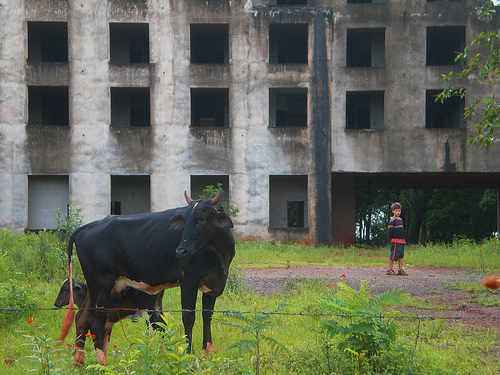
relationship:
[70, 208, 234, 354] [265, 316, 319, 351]
bull in grass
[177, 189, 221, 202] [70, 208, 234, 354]
horns on bull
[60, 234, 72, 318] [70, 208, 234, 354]
tail on bull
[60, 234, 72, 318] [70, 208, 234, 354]
tail of bull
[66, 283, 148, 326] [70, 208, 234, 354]
calf near bull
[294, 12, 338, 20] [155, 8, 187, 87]
concrete on wall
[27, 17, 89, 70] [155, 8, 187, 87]
window on wall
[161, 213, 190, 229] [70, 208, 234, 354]
ear of bull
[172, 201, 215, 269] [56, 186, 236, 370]
head of bull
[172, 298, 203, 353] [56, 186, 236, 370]
leg of bull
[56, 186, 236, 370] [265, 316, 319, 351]
bull in grass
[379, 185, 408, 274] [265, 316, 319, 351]
kid on grass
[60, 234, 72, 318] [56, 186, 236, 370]
tail on bull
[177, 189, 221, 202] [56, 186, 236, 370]
horns on bull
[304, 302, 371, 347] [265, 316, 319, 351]
fern in grass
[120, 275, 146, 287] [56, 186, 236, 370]
belly on bull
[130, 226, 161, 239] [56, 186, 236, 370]
rib of bull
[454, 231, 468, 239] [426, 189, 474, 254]
wire on gate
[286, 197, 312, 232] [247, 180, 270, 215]
door inside porch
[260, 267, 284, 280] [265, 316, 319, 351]
dirt in grass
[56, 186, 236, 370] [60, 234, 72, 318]
bull has tail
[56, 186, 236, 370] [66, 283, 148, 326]
bull near calf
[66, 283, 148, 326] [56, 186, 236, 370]
calf near bull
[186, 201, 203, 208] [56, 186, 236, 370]
spot on bull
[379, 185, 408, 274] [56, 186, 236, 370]
kid by bull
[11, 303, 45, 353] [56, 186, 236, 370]
flowers near bull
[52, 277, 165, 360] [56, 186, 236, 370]
calf behind bull